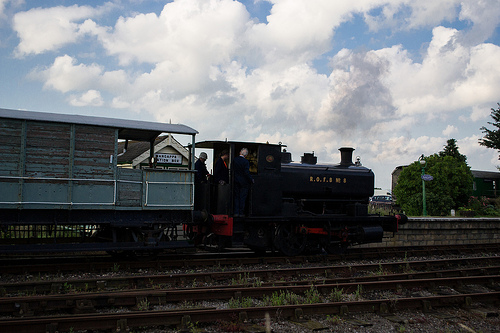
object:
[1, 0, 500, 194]
sky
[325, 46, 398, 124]
cloud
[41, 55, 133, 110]
cloud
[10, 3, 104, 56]
cloud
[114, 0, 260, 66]
cloud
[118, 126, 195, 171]
window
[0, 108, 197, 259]
train car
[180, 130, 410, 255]
train engine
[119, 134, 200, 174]
building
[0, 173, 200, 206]
railing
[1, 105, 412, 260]
train